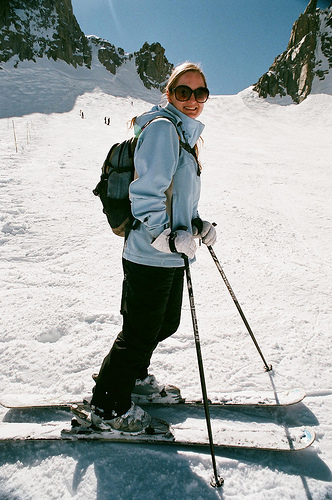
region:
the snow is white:
[9, 274, 100, 379]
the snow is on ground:
[10, 341, 90, 381]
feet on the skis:
[33, 378, 314, 464]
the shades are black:
[169, 79, 209, 107]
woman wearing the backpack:
[97, 67, 222, 277]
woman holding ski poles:
[136, 64, 275, 458]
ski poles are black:
[181, 298, 281, 398]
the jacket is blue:
[135, 126, 200, 264]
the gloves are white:
[156, 223, 221, 257]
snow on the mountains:
[267, 9, 329, 112]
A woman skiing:
[1, 37, 326, 497]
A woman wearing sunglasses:
[123, 62, 236, 231]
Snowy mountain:
[3, 3, 166, 88]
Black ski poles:
[173, 230, 314, 497]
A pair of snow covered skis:
[2, 373, 326, 474]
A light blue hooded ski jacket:
[122, 93, 232, 277]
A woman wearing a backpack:
[85, 56, 211, 270]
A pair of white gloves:
[149, 215, 220, 261]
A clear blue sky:
[101, 5, 285, 46]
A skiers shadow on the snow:
[2, 407, 322, 498]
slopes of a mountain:
[302, 27, 313, 46]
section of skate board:
[251, 441, 267, 451]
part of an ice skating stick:
[205, 413, 210, 443]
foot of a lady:
[119, 380, 128, 402]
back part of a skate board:
[40, 395, 49, 401]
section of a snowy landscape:
[126, 456, 138, 465]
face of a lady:
[182, 83, 208, 110]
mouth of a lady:
[186, 104, 195, 111]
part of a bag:
[113, 154, 129, 193]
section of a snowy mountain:
[83, 44, 103, 80]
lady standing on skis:
[13, 59, 269, 457]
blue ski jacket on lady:
[107, 104, 206, 283]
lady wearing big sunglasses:
[158, 63, 214, 109]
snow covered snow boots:
[81, 373, 193, 447]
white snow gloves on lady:
[153, 226, 197, 259]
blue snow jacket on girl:
[118, 97, 201, 275]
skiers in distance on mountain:
[68, 99, 114, 132]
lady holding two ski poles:
[163, 209, 276, 488]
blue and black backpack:
[91, 122, 137, 243]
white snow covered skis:
[1, 383, 309, 460]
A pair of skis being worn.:
[2, 371, 316, 458]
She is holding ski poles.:
[161, 203, 300, 495]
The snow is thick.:
[8, 196, 93, 359]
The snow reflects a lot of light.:
[6, 206, 87, 363]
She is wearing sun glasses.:
[93, 53, 234, 288]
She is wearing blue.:
[86, 55, 215, 281]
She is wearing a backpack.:
[93, 60, 223, 269]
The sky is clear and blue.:
[172, 7, 275, 53]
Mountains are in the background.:
[237, 0, 330, 97]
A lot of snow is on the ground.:
[219, 117, 329, 222]